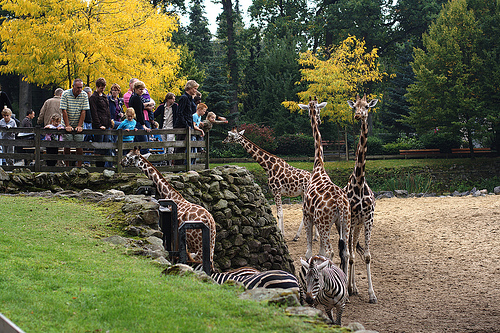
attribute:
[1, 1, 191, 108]
trees — yellow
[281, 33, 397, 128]
trees — yellow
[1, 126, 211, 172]
fence — rail, wood